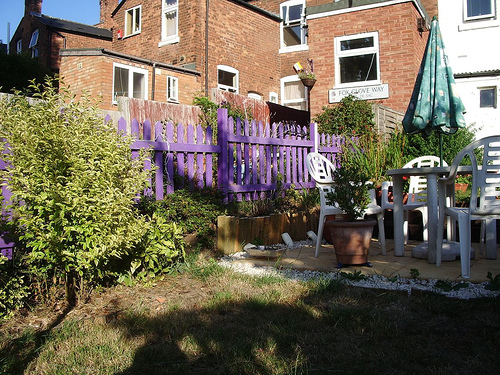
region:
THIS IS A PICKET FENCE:
[0, 96, 367, 280]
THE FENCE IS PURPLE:
[0, 108, 375, 270]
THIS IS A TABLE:
[375, 157, 479, 274]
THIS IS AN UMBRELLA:
[398, 10, 470, 150]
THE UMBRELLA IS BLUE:
[394, 13, 469, 148]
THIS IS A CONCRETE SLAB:
[251, 240, 499, 298]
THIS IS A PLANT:
[309, 136, 379, 286]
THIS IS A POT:
[323, 213, 375, 269]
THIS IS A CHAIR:
[435, 130, 499, 290]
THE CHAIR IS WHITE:
[431, 130, 498, 283]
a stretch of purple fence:
[214, 104, 318, 215]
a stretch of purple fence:
[319, 128, 362, 176]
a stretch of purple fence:
[103, 111, 213, 205]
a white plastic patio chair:
[304, 150, 389, 260]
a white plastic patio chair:
[432, 133, 497, 281]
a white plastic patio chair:
[383, 155, 453, 252]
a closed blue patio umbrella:
[403, 13, 468, 138]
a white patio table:
[379, 163, 486, 260]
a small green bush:
[4, 80, 152, 292]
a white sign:
[329, 83, 392, 103]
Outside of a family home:
[0, 3, 498, 373]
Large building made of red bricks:
[12, 0, 416, 105]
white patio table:
[387, 162, 450, 263]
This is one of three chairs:
[450, 132, 498, 277]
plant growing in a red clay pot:
[328, 150, 376, 266]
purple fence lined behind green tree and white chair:
[0, 115, 382, 200]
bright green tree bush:
[0, 85, 145, 275]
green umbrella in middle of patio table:
[402, 15, 464, 135]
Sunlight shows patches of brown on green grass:
[36, 280, 304, 372]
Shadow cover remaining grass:
[134, 275, 499, 370]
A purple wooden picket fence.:
[0, 109, 370, 260]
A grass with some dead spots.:
[3, 265, 498, 372]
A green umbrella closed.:
[401, 17, 468, 136]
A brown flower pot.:
[326, 219, 376, 266]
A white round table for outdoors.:
[383, 152, 498, 264]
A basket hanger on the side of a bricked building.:
[300, 59, 316, 86]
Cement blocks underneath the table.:
[254, 229, 498, 284]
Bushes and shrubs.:
[4, 87, 232, 307]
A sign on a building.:
[325, 81, 390, 99]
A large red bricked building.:
[7, 0, 439, 134]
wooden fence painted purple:
[95, 98, 318, 223]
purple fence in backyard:
[72, 79, 348, 219]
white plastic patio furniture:
[291, 114, 498, 315]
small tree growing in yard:
[5, 80, 195, 350]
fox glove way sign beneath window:
[315, 20, 402, 117]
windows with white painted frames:
[203, 8, 380, 116]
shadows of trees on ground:
[94, 231, 409, 373]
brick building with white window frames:
[7, 0, 324, 97]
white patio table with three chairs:
[297, 116, 491, 275]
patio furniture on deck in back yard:
[270, 105, 499, 285]